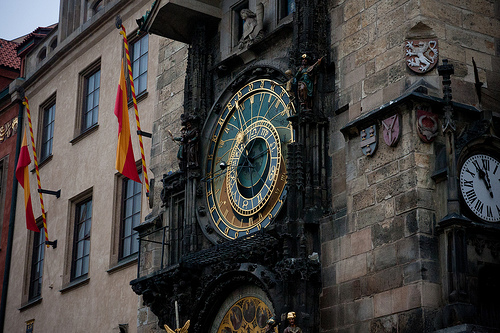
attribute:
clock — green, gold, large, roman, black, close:
[190, 57, 306, 244]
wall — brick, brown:
[337, 166, 420, 295]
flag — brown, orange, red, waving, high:
[86, 74, 160, 183]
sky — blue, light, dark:
[8, 2, 44, 22]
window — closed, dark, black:
[59, 65, 112, 142]